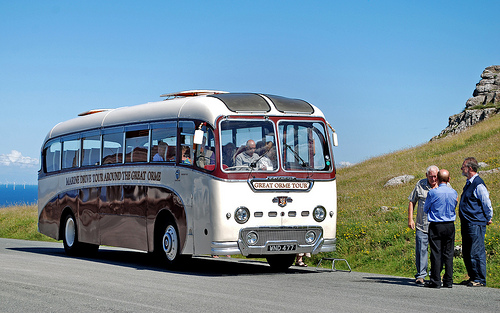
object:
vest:
[458, 173, 489, 225]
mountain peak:
[429, 65, 499, 141]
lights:
[304, 230, 316, 244]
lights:
[246, 231, 261, 245]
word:
[64, 176, 79, 185]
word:
[93, 172, 101, 182]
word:
[122, 170, 131, 180]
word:
[130, 170, 145, 180]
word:
[148, 170, 162, 180]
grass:
[336, 110, 498, 278]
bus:
[37, 89, 339, 270]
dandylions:
[361, 247, 369, 254]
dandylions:
[392, 232, 400, 239]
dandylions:
[404, 225, 411, 232]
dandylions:
[359, 228, 366, 235]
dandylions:
[343, 231, 350, 238]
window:
[221, 119, 277, 171]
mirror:
[193, 130, 203, 145]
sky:
[215, 18, 400, 64]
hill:
[335, 63, 498, 277]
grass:
[0, 202, 61, 242]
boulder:
[383, 174, 414, 186]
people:
[223, 139, 266, 171]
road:
[3, 237, 497, 312]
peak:
[1, 148, 41, 166]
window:
[148, 120, 180, 160]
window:
[122, 130, 149, 160]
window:
[100, 127, 125, 164]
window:
[60, 136, 80, 172]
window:
[44, 141, 61, 173]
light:
[313, 206, 327, 222]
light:
[234, 206, 251, 224]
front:
[213, 94, 339, 254]